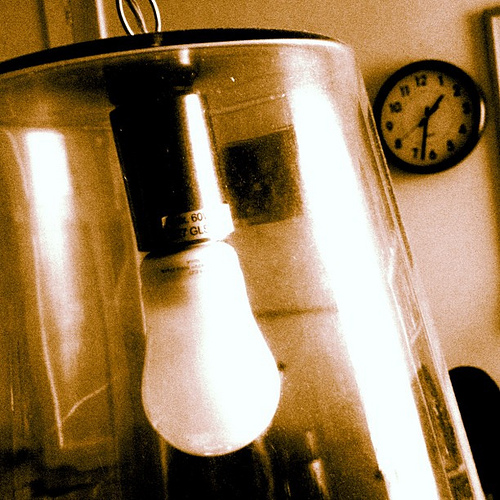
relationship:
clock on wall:
[370, 59, 487, 175] [3, 1, 496, 383]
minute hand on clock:
[420, 108, 432, 160] [370, 59, 487, 175]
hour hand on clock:
[425, 91, 444, 123] [370, 59, 487, 175]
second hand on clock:
[395, 115, 425, 146] [370, 59, 487, 175]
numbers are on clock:
[384, 73, 473, 162] [370, 59, 487, 175]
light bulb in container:
[141, 243, 285, 455] [2, 34, 487, 500]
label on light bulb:
[157, 259, 203, 280] [141, 243, 285, 455]